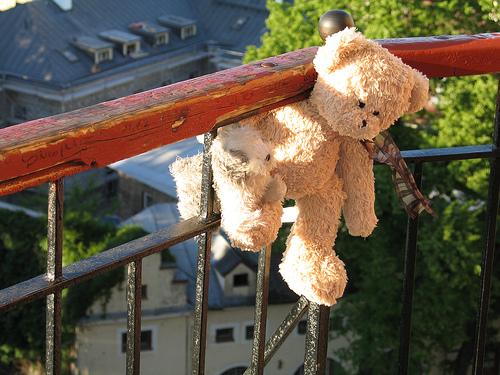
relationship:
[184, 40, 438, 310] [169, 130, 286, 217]
bear holding toy